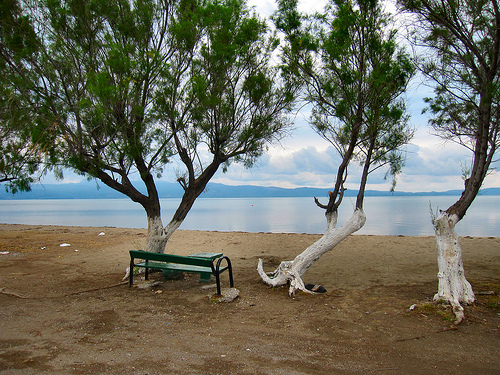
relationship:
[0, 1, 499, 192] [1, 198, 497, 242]
sky above water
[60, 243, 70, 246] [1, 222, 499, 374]
trash on beach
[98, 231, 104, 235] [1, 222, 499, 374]
trash on beach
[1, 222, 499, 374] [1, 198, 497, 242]
beach meets water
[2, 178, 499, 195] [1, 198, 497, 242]
mountains across water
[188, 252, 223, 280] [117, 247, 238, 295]
table in front of bench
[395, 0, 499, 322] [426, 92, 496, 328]
tree has a trunk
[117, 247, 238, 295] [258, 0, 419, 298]
bench near tree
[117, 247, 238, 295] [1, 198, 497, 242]
bench near water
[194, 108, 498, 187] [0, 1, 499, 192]
cloud in sky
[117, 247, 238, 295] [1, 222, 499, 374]
bench on beach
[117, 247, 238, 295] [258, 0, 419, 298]
bench behind tree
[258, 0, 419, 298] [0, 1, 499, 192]
tree against sky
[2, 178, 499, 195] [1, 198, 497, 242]
mountains are behind water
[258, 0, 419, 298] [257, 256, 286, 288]
tree has root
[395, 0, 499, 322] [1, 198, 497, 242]
tree near water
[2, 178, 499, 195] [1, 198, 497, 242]
mountains near water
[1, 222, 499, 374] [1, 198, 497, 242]
beach near water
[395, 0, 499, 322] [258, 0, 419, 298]
tree near tree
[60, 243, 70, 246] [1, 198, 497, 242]
trash near water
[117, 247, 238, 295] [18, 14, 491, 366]
bench from park